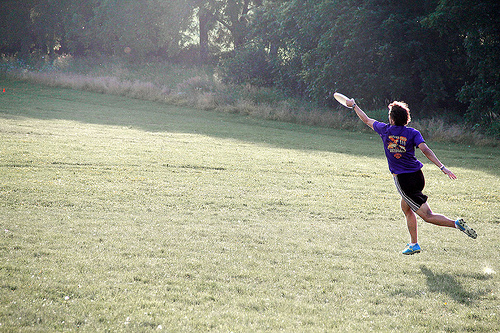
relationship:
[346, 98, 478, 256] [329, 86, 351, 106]
man reaching out to grab the disk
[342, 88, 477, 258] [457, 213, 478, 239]
man wearing cleats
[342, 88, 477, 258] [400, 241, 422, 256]
man wearing cleats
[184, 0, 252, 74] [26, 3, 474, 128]
tree in the woods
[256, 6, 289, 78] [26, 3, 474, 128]
tree in the woods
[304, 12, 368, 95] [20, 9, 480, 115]
tree in the woods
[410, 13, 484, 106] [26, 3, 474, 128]
tree in the woods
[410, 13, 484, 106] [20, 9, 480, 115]
tree in the woods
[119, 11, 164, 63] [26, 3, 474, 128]
tree in the woods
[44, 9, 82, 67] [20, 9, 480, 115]
tree in the woods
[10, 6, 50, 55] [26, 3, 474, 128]
tree in the woods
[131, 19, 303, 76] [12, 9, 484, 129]
tree in the woods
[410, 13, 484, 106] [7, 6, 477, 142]
tree in the woods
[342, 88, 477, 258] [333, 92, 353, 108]
man catches a disk